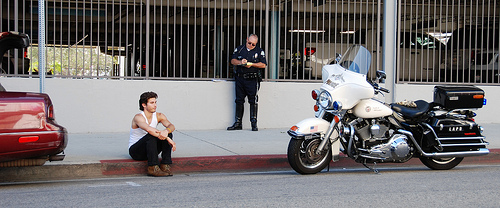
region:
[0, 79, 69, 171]
the back of a maroon car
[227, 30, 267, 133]
a policeman standing on the sidewalk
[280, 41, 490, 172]
a motorcycle is parked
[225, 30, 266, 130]
the policeman is wearing sunglasses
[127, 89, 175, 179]
a man sitting on the curb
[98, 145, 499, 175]
the curb is red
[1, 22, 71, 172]
the trunk of the car is open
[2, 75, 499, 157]
the wall and sidewalk is gray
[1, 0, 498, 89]
the wall has metal bars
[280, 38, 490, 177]
the motorcycle is black and white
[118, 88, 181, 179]
a man is sitting on the curb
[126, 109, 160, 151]
the man has a t-shirt on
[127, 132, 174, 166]
black jeans are on the man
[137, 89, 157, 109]
the boy has black hair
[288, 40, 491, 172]
a motorcycle is parked at the curb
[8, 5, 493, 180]
a parking lot is behind the street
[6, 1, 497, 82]
the parking lot fence is on a wall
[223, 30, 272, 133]
a motorcycle cop is standing on the sidewalk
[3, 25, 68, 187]
a red car is parked at the curb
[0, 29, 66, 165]
the trunk is open on the red car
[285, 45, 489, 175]
a black and white motorcycle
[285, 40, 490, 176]
a police motorcycle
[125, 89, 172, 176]
a man sitting on curb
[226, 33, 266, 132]
a police officer writing a ticket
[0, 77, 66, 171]
a parked red car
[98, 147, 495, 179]
a red painted curb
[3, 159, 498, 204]
a paved city street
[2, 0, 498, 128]
a parking garage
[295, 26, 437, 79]
a parked white truck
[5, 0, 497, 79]
metal bars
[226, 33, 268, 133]
a police officer on a sidewalk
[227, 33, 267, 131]
a police officer writing on paper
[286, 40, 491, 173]
a police motorcycle parked by a sidewalk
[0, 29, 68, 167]
a red car with an open trunk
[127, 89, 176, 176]
a man sitting on the sidewalk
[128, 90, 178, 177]
a man wearing a white tank top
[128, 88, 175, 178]
a man wearing a brown pair of shoes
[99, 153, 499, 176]
a red curb on a sidewalk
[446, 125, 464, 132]
LAPD on the side of a motorcycle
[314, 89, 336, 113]
a headlight on a motorcycle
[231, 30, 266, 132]
a policeman writing a ticket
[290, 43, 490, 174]
a policeman's motorcycle parked on the side of a street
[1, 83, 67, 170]
back of a red car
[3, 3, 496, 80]
a metal fence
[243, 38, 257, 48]
a policeman wearing black sunglasses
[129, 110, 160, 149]
a man wearing a white tank top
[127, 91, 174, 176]
a man sitting on the side of a sidewalk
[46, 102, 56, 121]
red taillight of a red car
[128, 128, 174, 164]
a man wearing black pants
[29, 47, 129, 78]
opened door of a garage